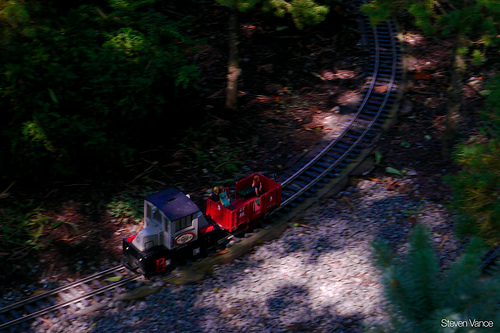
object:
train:
[119, 171, 293, 269]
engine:
[124, 188, 216, 275]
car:
[207, 173, 285, 231]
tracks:
[5, 7, 428, 330]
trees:
[371, 155, 500, 319]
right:
[452, 6, 498, 331]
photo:
[0, 2, 498, 332]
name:
[436, 318, 497, 328]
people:
[214, 184, 232, 207]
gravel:
[253, 258, 375, 312]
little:
[250, 175, 264, 198]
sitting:
[252, 175, 262, 194]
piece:
[207, 225, 231, 242]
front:
[115, 223, 167, 278]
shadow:
[102, 283, 334, 333]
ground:
[83, 25, 461, 135]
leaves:
[6, 6, 96, 72]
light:
[57, 277, 93, 307]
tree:
[215, 3, 263, 115]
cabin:
[131, 188, 205, 251]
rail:
[281, 19, 403, 203]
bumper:
[117, 258, 146, 274]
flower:
[105, 29, 151, 55]